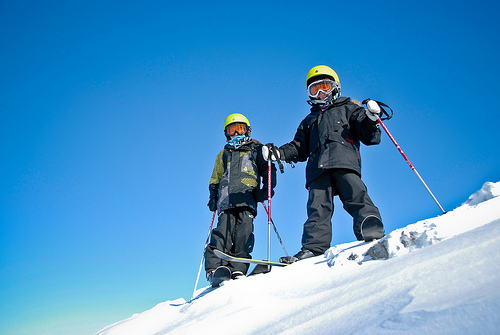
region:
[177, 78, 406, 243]
two people on a ski hill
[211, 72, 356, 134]
two people wearing yellow helmets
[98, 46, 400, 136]
bright blue sky over skiers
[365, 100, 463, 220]
red and silver ski pole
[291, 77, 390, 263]
person in dark jacket and black snow pants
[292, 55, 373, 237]
person in black snow pants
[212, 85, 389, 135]
two people wearing ski goggles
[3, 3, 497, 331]
blue of daytime sky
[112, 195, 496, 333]
snow on sloped hill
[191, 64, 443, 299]
two skiers on snow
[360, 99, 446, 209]
white mitten on pole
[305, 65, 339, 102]
yellow helmet on head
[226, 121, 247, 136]
goggles with orange tint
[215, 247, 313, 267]
boot on top of ski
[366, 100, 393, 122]
straps on ski pole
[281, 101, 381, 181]
front of winter coat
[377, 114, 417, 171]
red design on pole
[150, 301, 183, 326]
white snow on ground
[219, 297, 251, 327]
white snow on ground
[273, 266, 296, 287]
white snow on ground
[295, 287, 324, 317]
white snow on ground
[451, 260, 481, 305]
white snow on ground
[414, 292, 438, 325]
white snow on ground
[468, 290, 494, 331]
white snow on ground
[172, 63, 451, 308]
two people are standing with the snow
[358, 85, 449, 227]
a person holding snow pole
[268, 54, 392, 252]
person with snow suit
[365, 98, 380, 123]
white color gloves in the man's hand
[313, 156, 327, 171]
button of the snowsuit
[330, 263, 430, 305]
a place full of snow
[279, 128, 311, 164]
elbow of the person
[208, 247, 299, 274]
black color skate board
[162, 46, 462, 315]
KIB [Kids In Black]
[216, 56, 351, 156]
the yellow helmets make it official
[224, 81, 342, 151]
or maybe the yellow helmets with the orange goggles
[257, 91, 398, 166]
two staunch white mittens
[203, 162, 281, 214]
two long black ski-plumber gloves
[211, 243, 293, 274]
a ski. yellowy. half in the air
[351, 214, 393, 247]
ski's black bottom